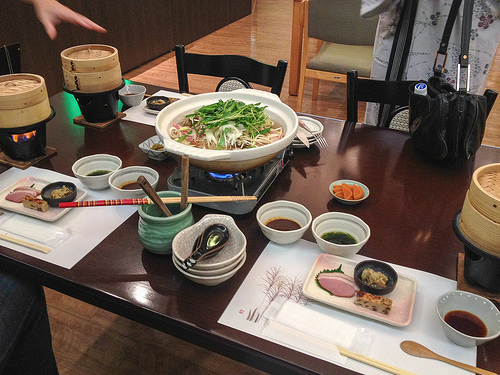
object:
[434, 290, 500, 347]
bowl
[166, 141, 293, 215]
burner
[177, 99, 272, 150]
vegetables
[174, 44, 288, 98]
chair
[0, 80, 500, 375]
table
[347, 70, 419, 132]
chair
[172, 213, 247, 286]
bowls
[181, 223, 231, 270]
spoon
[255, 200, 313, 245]
bowl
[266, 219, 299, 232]
sauce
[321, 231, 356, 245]
sauce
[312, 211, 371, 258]
bowl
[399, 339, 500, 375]
spoon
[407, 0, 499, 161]
bag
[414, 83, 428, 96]
bottle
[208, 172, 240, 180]
flame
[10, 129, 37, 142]
flame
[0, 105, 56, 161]
stove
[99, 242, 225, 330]
shadow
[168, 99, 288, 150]
food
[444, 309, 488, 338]
soup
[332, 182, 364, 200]
oranges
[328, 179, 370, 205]
bowl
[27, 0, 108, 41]
hand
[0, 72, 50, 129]
boxes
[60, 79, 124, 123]
flame heaters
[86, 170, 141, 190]
two dishes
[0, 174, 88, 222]
rectangular plate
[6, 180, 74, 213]
items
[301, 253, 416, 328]
dishes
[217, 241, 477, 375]
mat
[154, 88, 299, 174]
bowl/food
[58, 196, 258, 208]
wooden chopsticks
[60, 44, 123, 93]
bamboo container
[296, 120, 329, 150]
fork tines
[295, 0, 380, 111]
cushioned chair